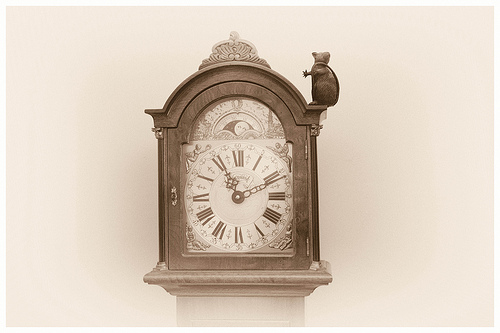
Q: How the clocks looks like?
A: Old fashioned.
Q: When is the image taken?
A: Time is 11.10.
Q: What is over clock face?
A: Glass door.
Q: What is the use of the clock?
A: Time.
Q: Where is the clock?
A: On tower.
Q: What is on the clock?
A: Animal.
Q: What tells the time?
A: Arms.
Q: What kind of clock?
A: Antique.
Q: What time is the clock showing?
A: 11:11.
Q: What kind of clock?
A: Grandfather.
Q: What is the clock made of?
A: Wood.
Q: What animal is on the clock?
A: Mouse.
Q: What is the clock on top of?
A: Pole.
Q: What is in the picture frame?
A: An old clock.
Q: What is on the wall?
A: A clock that is old.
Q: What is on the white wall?
A: An old clock.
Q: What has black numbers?
A: The clock.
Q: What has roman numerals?
A: The clock.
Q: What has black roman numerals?
A: The old clock.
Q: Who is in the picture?
A: No one.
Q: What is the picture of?
A: Clock.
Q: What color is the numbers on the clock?
A: Light brown.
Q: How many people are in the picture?
A: None.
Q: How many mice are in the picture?
A: One.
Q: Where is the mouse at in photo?
A: Right side of the clock.